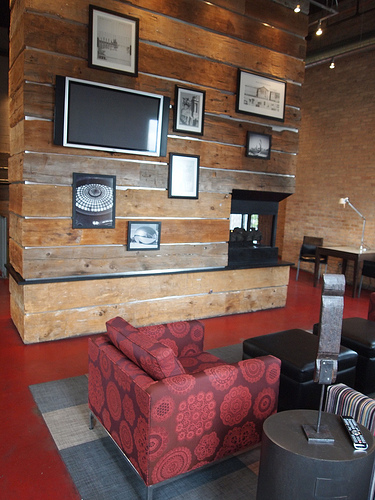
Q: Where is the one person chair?
A: The living room.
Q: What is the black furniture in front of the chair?
A: An ottoman.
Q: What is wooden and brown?
A: A wall.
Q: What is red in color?
A: A chair.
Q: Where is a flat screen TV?
A: On the wall.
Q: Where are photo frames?
A: Hanging on the wall.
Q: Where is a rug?
A: On the floor.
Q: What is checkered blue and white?
A: Rug.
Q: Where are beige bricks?
A: On the wall.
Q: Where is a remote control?
A: On round table.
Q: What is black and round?
A: Small table.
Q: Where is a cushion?
A: On red chair.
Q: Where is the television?
A: On the wall.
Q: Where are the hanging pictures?
A: On the wall.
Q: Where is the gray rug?
A: Under the red chair.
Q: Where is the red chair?
A: Next to the square ottomans.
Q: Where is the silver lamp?
A: On the table against the brick wall.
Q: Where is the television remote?
A: On the circular table.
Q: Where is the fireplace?
A: On the corner of the wall.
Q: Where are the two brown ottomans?
A: In front of the red chair.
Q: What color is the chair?
A: Red.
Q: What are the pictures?
A: Walls.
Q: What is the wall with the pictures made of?
A: Wood.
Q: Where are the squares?
A: Floor.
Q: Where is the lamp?
A: Table.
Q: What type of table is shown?
A: Wood.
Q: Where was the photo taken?
A: In a lobby.